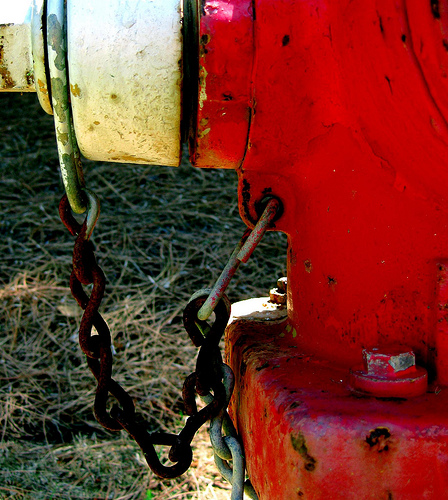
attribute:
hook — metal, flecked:
[197, 201, 275, 335]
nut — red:
[347, 343, 427, 399]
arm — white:
[2, 0, 184, 164]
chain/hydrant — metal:
[44, 80, 392, 487]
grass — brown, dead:
[109, 186, 215, 280]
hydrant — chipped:
[183, 89, 364, 311]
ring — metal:
[44, 0, 95, 221]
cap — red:
[344, 343, 429, 401]